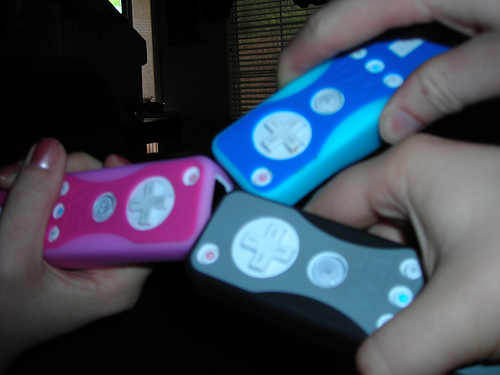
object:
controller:
[45, 162, 235, 264]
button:
[182, 164, 203, 187]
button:
[56, 178, 71, 195]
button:
[51, 204, 66, 219]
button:
[47, 224, 63, 241]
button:
[129, 178, 175, 225]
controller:
[190, 188, 430, 342]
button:
[198, 243, 219, 263]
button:
[237, 222, 298, 275]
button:
[401, 256, 425, 280]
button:
[387, 283, 413, 308]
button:
[376, 311, 395, 330]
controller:
[203, 28, 449, 206]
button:
[351, 46, 367, 61]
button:
[367, 58, 382, 75]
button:
[384, 72, 403, 90]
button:
[309, 88, 351, 114]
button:
[250, 108, 310, 159]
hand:
[1, 138, 151, 368]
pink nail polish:
[31, 139, 62, 172]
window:
[214, 2, 329, 144]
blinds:
[230, 2, 302, 103]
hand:
[276, 2, 499, 146]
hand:
[295, 135, 499, 374]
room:
[3, 4, 496, 373]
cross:
[129, 182, 169, 225]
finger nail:
[29, 137, 65, 169]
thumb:
[3, 137, 67, 277]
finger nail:
[109, 152, 131, 168]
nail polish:
[114, 156, 131, 169]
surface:
[190, 187, 422, 332]